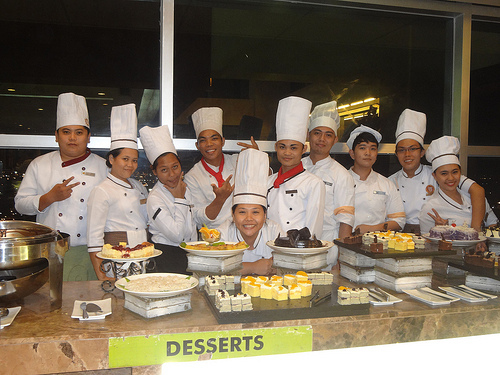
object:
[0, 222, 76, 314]
pot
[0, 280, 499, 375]
counter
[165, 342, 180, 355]
letter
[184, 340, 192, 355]
letter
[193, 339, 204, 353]
letter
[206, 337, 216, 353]
letter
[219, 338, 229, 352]
letter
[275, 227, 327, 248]
desserts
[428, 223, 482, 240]
desserts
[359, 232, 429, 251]
desserts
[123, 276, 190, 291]
desserts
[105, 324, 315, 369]
sign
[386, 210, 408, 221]
beige stripes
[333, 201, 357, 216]
beige stripes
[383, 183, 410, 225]
sleeve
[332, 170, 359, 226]
sleeve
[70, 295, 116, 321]
platter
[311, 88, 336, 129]
ground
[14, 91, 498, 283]
group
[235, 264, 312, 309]
blue laces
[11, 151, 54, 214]
arm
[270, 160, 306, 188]
fabric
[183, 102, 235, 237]
chefs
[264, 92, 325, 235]
chefs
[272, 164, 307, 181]
red scarves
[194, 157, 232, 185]
red scarves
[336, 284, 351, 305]
dessert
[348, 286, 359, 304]
dessert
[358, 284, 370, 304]
dessert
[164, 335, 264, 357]
letters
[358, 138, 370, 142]
hair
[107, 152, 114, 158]
hair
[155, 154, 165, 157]
hair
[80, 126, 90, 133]
hair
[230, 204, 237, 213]
hair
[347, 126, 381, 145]
hat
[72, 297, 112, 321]
napkin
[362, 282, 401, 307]
napkin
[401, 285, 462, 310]
napkin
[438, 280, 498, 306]
napkin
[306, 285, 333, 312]
tongs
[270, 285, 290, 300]
dessert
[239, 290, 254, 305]
dessert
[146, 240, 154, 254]
dessert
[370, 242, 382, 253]
dessert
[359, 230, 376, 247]
dessert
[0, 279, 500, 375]
marble table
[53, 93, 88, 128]
chef hat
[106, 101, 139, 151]
chef hat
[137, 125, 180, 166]
chef hat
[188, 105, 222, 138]
chef hat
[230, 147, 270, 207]
chef hat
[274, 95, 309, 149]
chef hat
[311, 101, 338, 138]
chef hat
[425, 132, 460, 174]
chef hat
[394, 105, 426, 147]
chef hat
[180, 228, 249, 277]
dessert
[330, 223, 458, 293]
dessert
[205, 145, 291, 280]
chef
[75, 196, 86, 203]
button